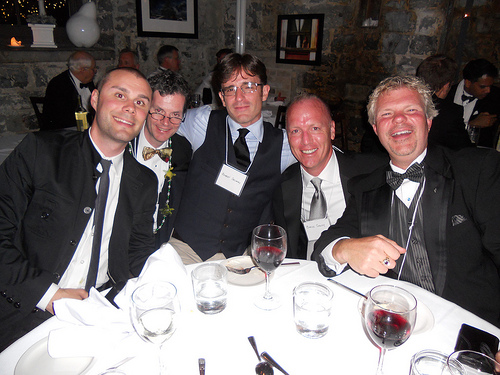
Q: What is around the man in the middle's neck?
A: A pass.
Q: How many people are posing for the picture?
A: 5.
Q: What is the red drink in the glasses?
A: Wine.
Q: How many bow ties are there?
A: 2.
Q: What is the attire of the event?
A: Formal.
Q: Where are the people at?
A: Restaurant.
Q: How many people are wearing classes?
A: 2.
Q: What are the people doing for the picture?
A: Smiling.